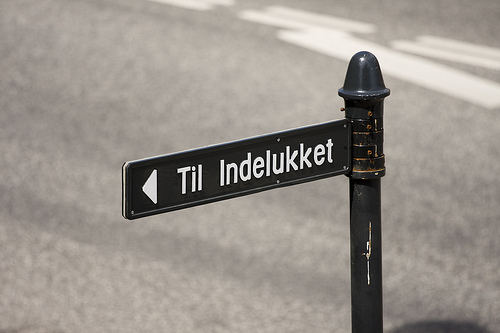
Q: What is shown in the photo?
A: Street sign.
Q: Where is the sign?
A: Street.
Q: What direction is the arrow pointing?
A: Left.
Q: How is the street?
A: Paved.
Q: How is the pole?
A: Black.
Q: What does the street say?
A: Til indelukket.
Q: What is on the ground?
A: Pavement.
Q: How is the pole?
A: Tall.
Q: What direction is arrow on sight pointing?
A: To left.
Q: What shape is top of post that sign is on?
A: Bell shaped.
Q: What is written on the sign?
A: Til Indelukket.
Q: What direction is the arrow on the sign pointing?
A: Left.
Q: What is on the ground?
A: White lines.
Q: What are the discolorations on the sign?
A: Rust.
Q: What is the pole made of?
A: Metal.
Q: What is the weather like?
A: Sunny.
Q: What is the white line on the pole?
A: Scratch.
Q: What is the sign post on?
A: The road.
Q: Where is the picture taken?
A: A road.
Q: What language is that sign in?
A: In German.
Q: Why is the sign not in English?
A: Because it's in Germany.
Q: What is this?
A: A street sign.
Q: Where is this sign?
A: Beside the street.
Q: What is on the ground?
A: The road.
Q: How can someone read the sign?
A: By knowing German.